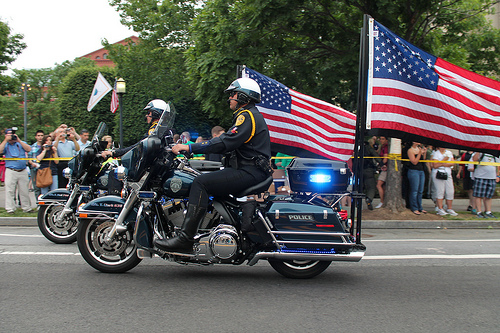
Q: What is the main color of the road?
A: Gray.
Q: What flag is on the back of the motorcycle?
A: USA.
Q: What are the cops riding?
A: Motorcycles.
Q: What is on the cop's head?
A: Helmet.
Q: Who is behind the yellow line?
A: Parade watchers.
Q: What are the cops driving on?
A: Road.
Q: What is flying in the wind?
A: Flag.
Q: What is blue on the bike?
A: Light.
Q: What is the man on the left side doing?
A: Taking a picture.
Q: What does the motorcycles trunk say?
A: Police.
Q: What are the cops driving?
A: Motorcycle.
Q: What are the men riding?
A: Motorcycles.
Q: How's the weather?
A: Cloudy and cool.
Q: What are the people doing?
A: Standing on the sidewalk.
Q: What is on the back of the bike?
A: A flag.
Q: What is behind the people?
A: Trees.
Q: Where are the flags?
A: On motorcycles.